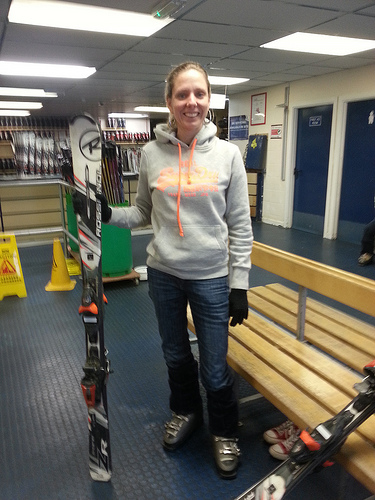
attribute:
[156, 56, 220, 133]
hair — light, straight, blonde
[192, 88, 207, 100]
eye — dark, open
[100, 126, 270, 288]
hoodie — white, grey, gray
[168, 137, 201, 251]
tie — orange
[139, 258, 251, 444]
pants — denim, blue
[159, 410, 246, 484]
sneakers — grey, red, white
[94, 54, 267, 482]
women — smiling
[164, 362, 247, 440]
leg warmers — black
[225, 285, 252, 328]
gloves — black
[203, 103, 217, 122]
earrings — silver, large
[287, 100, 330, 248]
door — blue, white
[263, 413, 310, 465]
sneakers — red, white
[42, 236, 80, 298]
cone — yellow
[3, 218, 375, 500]
floor — blue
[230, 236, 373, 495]
bench — wooden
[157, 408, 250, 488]
boots — silver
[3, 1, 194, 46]
lights — florescent, on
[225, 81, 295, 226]
wall — white